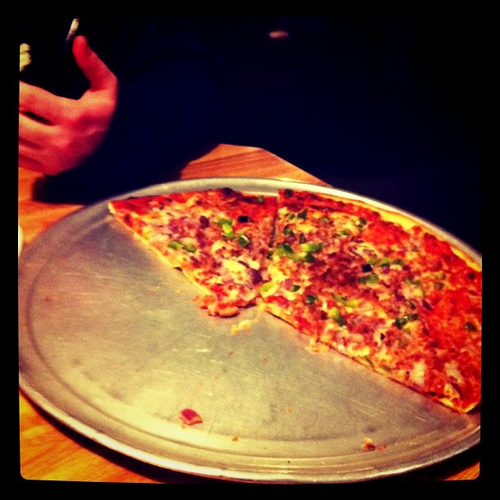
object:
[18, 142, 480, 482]
table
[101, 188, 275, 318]
pizza slice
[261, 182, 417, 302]
pizza slice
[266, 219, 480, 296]
pizza slice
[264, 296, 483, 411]
pizza slice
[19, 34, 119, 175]
hand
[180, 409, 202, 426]
topping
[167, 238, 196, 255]
pepper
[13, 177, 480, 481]
pan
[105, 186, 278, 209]
pizza crust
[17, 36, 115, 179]
hand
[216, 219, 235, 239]
topping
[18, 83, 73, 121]
pointer finger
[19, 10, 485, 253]
human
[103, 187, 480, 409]
half pizza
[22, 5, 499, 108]
background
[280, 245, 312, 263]
peppers